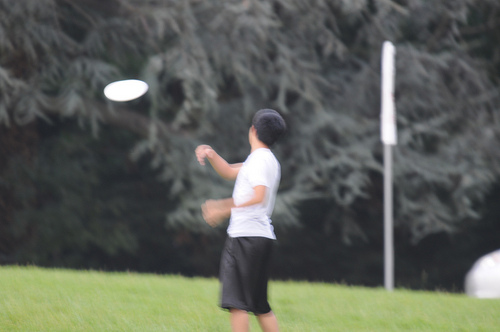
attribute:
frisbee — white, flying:
[102, 65, 162, 104]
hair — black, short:
[241, 109, 289, 146]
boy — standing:
[195, 97, 279, 330]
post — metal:
[373, 35, 404, 292]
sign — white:
[370, 33, 407, 156]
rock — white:
[461, 236, 499, 308]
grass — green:
[282, 280, 497, 329]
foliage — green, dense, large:
[8, 2, 494, 282]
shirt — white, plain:
[230, 146, 286, 246]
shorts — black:
[221, 227, 281, 324]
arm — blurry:
[198, 183, 270, 224]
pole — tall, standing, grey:
[374, 145, 398, 300]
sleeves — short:
[249, 151, 275, 187]